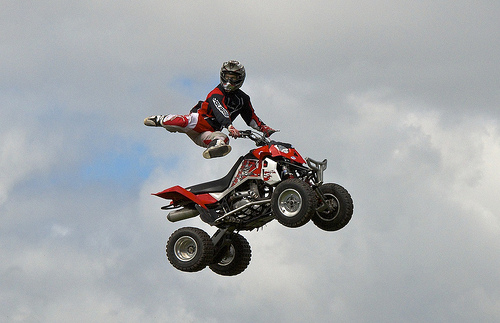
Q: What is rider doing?
A: Jumping.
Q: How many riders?
A: One.